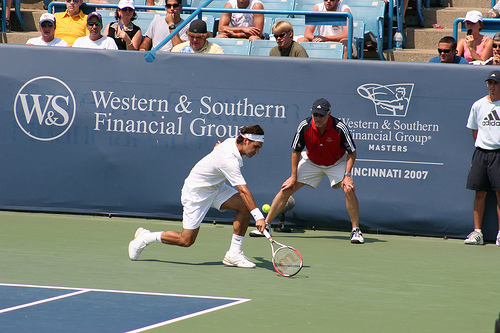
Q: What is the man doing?
A: Playing tennis.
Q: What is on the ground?
A: A tennis racket.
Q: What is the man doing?
A: Watching the player.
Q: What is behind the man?
A: A blue wall.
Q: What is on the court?
A: Blue and white colors.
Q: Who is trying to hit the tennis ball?
A: A man.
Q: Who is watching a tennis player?
A: A man.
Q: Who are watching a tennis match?
A: Spectators.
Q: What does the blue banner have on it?
A: Company logos.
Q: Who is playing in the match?
A: A male tennis player.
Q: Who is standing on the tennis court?
A: A man.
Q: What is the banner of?
A: Advertisements.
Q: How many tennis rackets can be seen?
A: 1.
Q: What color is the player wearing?
A: White.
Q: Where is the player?
A: On a tennis court.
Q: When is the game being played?
A: Daytime.